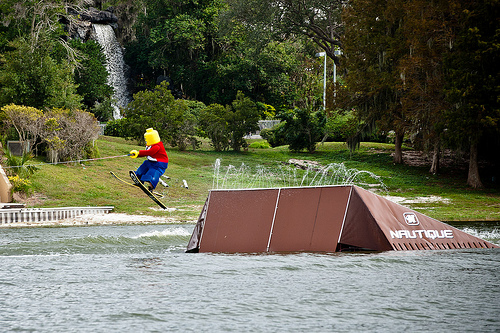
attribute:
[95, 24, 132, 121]
waterfall — real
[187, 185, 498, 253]
ramp — brown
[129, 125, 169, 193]
skier — dressed, jumping, costumed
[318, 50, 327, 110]
posts — tall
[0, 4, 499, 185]
trees — old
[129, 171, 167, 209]
skis — real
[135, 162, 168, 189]
pants — blue, red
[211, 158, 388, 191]
spray — curved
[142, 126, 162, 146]
bucket — yellow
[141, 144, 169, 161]
shirt — real, red